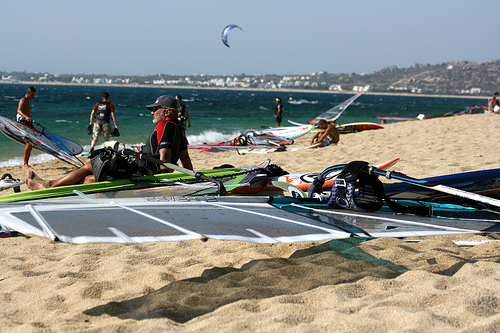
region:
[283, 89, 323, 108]
small white wave on water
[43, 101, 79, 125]
tranquil turquoise water in the bay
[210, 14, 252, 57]
shiny silver and blue kite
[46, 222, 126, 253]
white edge of surf board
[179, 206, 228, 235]
solid gray bottom of surf board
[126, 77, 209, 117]
gray and white cap on man's head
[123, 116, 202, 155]
red edge of wet suit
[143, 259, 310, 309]
footprints in the brown sand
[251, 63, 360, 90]
white houses in the background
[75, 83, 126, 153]
man walking on the sand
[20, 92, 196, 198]
older dude w/ dark suntan on sand near surf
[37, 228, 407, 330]
a dark rectangular shadow strangely turning green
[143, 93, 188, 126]
the white beard+blue black baseball cap of a way older dude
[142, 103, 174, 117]
the ear+sunglasses of the same middle-aged man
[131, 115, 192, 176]
red+black wetsuit top w/ white trim+logo on sleeve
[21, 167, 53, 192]
two bare, sandy, aging tanned feet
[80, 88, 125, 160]
younger dude w/ black backpackon back+black swim fins on hands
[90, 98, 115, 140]
red t-shirt, khaki shorts of swim fin'd dude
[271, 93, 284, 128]
person clad in black, yellow headband, staring at beautiful green water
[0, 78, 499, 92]
that long stretch of sand on the other side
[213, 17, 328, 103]
Kite surfer in the background.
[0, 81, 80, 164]
Man holds his sail-board.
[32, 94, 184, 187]
Bearded man lounges on beach.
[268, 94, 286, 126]
Lady looks into the sea.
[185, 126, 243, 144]
The waves washing ashore.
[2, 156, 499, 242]
Surfing equipment litter the beach.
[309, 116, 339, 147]
A man sits crouched over.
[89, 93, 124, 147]
A man walks along the beach.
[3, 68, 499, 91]
Beach-side homes dot the landscape.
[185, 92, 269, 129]
The water is very choppy.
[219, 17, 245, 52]
blue and white kite in sky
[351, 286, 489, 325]
patch of tan sand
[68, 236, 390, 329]
shadow of wing from flying device on tan sand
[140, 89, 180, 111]
black baseball cap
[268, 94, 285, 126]
person in shorts standing on sand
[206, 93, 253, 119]
green and blue ocean water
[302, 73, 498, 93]
houses and organic structures in horizon beyond body of water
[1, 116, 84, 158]
grey and blue surfboard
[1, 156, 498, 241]
green, white and blue flying device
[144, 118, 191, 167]
red, black and grey short sleeve shirt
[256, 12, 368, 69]
this is the sky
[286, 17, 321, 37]
the sky is blue in color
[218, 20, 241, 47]
this is a kite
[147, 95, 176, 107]
this is a cap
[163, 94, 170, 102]
the cap is black in color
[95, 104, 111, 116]
this is a bag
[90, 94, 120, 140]
this is a man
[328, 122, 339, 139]
the man is bare chested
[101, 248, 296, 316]
this is a sandy beach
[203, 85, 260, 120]
this is an ocean